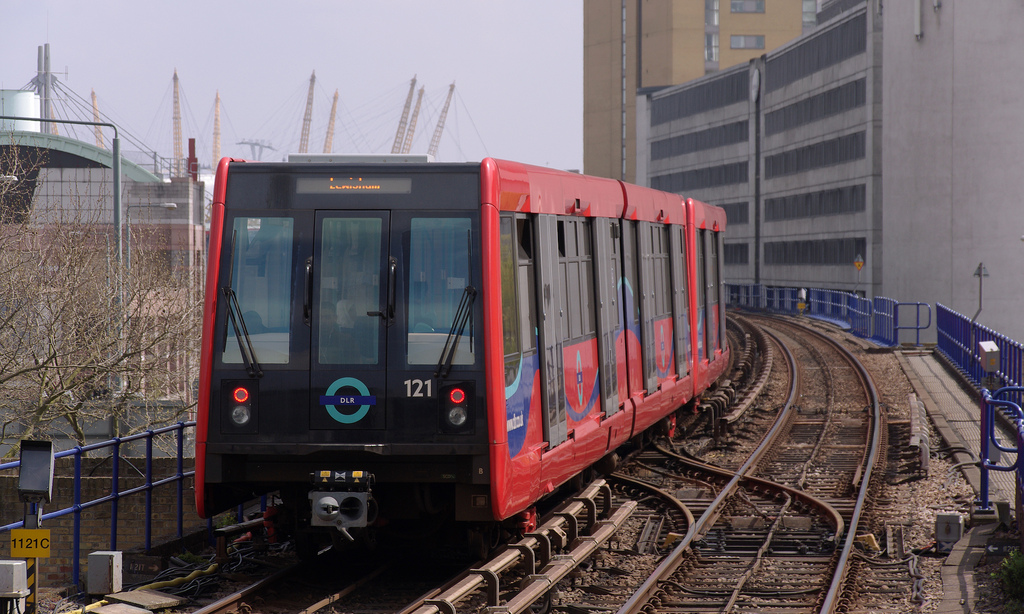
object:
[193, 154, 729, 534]
train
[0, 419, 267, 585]
fence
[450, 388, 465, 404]
light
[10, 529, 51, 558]
sign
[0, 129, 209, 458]
tree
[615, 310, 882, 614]
tracks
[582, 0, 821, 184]
building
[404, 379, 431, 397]
number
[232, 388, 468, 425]
lights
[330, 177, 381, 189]
destination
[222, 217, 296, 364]
window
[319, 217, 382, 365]
window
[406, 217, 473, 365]
window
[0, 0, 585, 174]
sky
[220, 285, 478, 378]
wipers